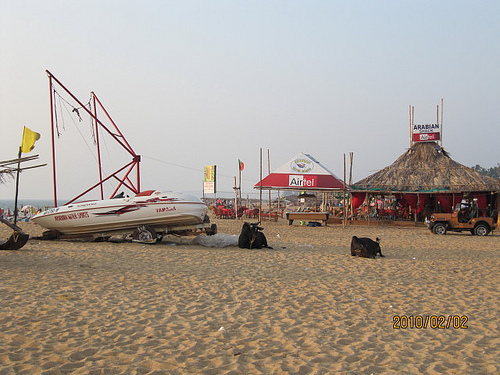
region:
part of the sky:
[291, 32, 358, 93]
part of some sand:
[288, 305, 338, 361]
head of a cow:
[246, 215, 265, 241]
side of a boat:
[78, 205, 155, 223]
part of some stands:
[332, 180, 352, 214]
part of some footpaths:
[308, 331, 345, 359]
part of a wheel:
[132, 232, 155, 246]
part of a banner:
[409, 119, 441, 145]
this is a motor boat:
[35, 180, 205, 245]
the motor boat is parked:
[30, 177, 204, 234]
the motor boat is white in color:
[26, 175, 208, 244]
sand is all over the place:
[7, 274, 498, 369]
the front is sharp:
[32, 205, 62, 229]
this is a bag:
[346, 233, 387, 265]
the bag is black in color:
[348, 231, 383, 258]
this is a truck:
[426, 201, 495, 235]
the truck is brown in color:
[427, 199, 496, 236]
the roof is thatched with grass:
[404, 145, 441, 184]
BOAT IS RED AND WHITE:
[29, 68, 219, 248]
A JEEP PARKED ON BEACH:
[423, 199, 498, 238]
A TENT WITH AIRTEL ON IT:
[252, 146, 355, 228]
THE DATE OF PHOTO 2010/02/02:
[390, 311, 473, 331]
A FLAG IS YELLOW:
[19, 121, 41, 156]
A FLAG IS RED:
[236, 158, 245, 170]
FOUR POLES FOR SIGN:
[408, 96, 445, 147]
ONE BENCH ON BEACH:
[282, 208, 332, 227]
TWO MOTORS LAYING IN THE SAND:
[236, 220, 384, 260]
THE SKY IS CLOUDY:
[1, 0, 499, 198]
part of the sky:
[372, 26, 419, 66]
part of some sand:
[276, 313, 324, 353]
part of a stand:
[330, 195, 350, 230]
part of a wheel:
[135, 227, 155, 242]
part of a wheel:
[433, 225, 455, 237]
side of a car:
[447, 212, 468, 227]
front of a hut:
[383, 194, 409, 229]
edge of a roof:
[398, 185, 425, 197]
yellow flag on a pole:
[13, 118, 46, 171]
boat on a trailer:
[27, 183, 212, 240]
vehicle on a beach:
[420, 194, 497, 245]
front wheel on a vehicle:
[427, 218, 450, 238]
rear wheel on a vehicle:
[470, 220, 491, 240]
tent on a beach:
[242, 143, 357, 232]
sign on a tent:
[285, 171, 321, 191]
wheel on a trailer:
[128, 221, 163, 253]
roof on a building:
[341, 128, 498, 196]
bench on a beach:
[279, 208, 336, 231]